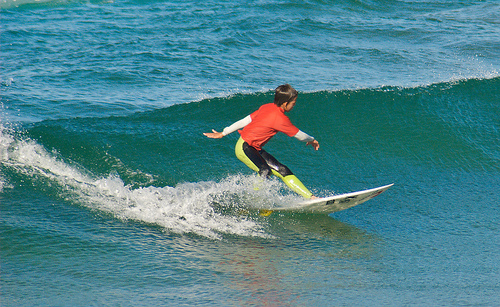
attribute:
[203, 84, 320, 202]
boy — young, surfing, wet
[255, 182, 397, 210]
surfboard — white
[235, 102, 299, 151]
shirt — orange, white, red, red ad white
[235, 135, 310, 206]
pants — black, yellow, neon yello, green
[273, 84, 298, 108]
hair — short, brown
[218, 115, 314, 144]
sleeves — white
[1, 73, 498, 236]
wave — small, surfable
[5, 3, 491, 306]
water — blue, moving, green